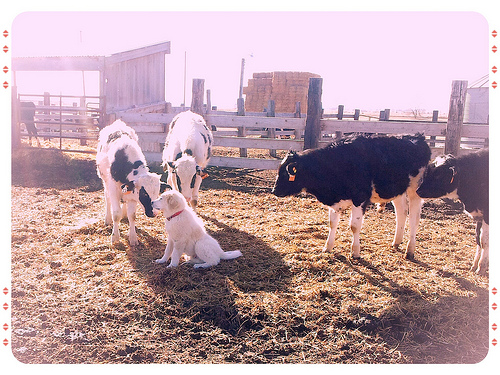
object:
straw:
[12, 271, 110, 362]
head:
[416, 152, 456, 201]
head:
[270, 146, 303, 197]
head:
[167, 156, 209, 201]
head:
[121, 173, 173, 218]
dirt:
[316, 278, 409, 352]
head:
[151, 191, 186, 212]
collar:
[165, 210, 184, 221]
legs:
[348, 204, 366, 260]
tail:
[221, 249, 244, 260]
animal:
[150, 189, 243, 268]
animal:
[271, 132, 432, 260]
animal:
[415, 148, 488, 276]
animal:
[161, 109, 213, 210]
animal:
[95, 119, 172, 245]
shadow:
[335, 252, 492, 364]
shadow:
[197, 199, 289, 294]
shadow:
[11, 141, 98, 194]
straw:
[243, 70, 321, 112]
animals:
[92, 109, 488, 276]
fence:
[106, 76, 486, 196]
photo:
[43, 27, 473, 340]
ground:
[90, 212, 329, 343]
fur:
[186, 223, 206, 246]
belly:
[368, 188, 405, 204]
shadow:
[128, 228, 243, 336]